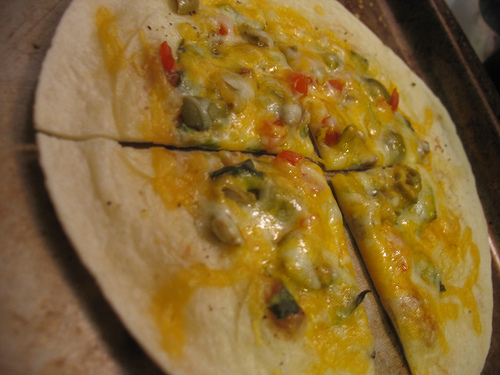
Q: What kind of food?
A: Pizza.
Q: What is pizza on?
A: Table.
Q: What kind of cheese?
A: Orange and white.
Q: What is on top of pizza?
A: Glaze.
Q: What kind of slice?
A: Vertical.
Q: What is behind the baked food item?
A: A metal pan.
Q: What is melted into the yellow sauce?
A: The vegetables.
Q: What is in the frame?
A: A piece of pizza.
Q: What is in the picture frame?
A: A piece of pizza.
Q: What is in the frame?
A: A piece of pizza.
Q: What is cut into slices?
A: The pizza.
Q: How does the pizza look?
A: It is cut into pieces.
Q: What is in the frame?
A: A slice of pizza.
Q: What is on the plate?
A: Quesadilla.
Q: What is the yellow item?
A: Cheese.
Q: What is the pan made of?
A: Metal.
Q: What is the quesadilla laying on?
A: Pan.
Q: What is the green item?
A: Peppers.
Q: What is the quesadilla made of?
A: Tortilla.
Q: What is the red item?
A: Peppers.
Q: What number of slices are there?
A: 4.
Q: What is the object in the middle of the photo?
A: Food.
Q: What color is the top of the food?
A: Yellow.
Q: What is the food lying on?
A: Tray.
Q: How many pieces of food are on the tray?
A: One.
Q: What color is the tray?
A: Silver.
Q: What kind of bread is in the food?
A: Pita.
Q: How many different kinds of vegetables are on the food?
A: Two.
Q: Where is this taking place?
A: In the kitchen.